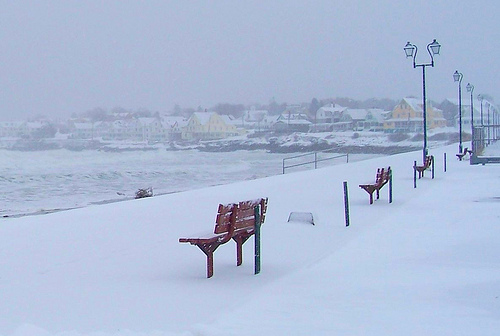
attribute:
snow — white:
[6, 218, 94, 335]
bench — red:
[179, 192, 271, 283]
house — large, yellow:
[389, 93, 438, 129]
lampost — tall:
[397, 28, 443, 166]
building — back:
[311, 101, 357, 131]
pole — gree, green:
[386, 165, 396, 202]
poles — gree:
[405, 154, 436, 198]